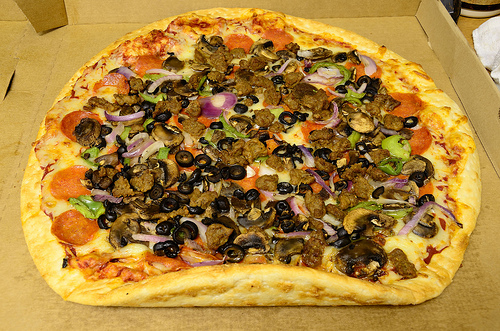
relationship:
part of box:
[17, 1, 69, 36] [0, 1, 499, 329]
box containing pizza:
[0, 1, 499, 329] [22, 7, 483, 306]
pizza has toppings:
[22, 7, 483, 306] [338, 117, 419, 220]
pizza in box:
[22, 7, 483, 306] [0, 1, 499, 329]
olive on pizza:
[176, 148, 193, 167] [22, 7, 483, 306]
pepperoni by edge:
[53, 208, 99, 246] [27, 190, 40, 222]